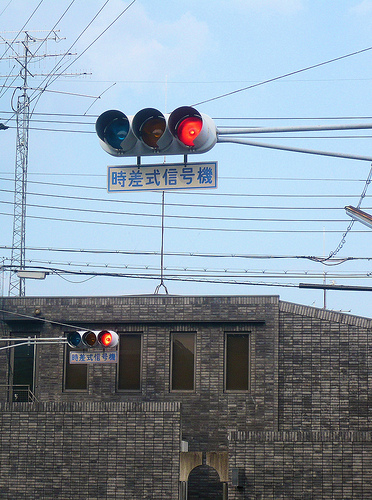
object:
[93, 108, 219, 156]
traffic light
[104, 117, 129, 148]
colors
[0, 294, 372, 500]
building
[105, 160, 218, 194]
sign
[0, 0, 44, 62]
wires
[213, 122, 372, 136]
pole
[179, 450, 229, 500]
archway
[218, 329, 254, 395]
windows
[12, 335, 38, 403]
door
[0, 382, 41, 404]
railing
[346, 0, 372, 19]
clouds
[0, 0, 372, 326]
sky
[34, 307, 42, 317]
light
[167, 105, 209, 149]
light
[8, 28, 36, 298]
antenna